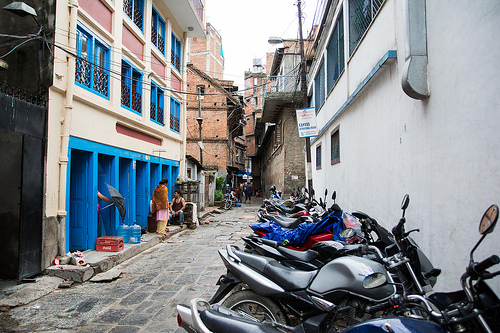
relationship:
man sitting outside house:
[167, 187, 185, 227] [40, 4, 207, 287]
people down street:
[212, 166, 254, 211] [181, 215, 207, 317]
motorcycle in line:
[181, 206, 498, 327] [246, 180, 376, 331]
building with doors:
[33, 26, 258, 250] [62, 132, 209, 265]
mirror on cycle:
[477, 204, 497, 239] [184, 228, 402, 333]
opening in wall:
[248, 147, 268, 187] [56, 0, 187, 260]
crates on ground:
[90, 232, 126, 249] [29, 159, 297, 318]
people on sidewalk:
[150, 171, 194, 239] [69, 227, 122, 269]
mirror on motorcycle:
[471, 200, 498, 234] [181, 206, 498, 327]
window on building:
[71, 51, 92, 86] [44, 0, 186, 253]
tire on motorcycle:
[204, 278, 283, 328] [200, 240, 392, 308]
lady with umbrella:
[97, 187, 115, 229] [103, 179, 127, 219]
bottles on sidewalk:
[119, 217, 139, 241] [44, 222, 188, 279]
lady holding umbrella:
[93, 187, 109, 237] [101, 180, 127, 223]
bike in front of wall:
[244, 222, 431, 266] [303, 12, 498, 296]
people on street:
[171, 171, 269, 222] [84, 170, 244, 330]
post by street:
[190, 76, 235, 209] [32, 167, 288, 321]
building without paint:
[35, 56, 200, 227] [45, 187, 64, 217]